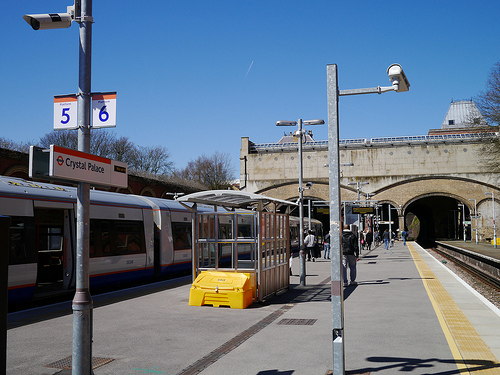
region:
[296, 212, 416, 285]
people walking along side of the tracks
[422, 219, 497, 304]
no train on the tracks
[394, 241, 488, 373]
thick yellow line on the ground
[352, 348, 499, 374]
shadow on the ground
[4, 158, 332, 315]
train on the tracks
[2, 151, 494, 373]
train at the station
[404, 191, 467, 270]
tracks running into a tunnel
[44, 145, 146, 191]
white sign on the pole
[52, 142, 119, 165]
red stripe at the top of the sign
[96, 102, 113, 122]
blue number on a white background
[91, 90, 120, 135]
the number 6 sign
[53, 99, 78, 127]
the number five sign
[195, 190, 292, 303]
the train waiting station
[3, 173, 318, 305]
the train on the side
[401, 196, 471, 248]
the hole for the train the in the wall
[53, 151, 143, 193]
the crystal palace sign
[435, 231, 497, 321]
the railway tracks on the right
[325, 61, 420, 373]
the light post in the front right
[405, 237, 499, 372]
the yellow cement line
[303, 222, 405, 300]
the people waiting in the background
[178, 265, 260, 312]
a yellow box on concrete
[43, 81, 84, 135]
A sign with the number 5 on a pole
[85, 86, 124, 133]
A sign with the number 6 on a pole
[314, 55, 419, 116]
a light at the top of a pole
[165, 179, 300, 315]
A covered area at a train station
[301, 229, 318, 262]
A person waiting for a train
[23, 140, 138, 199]
A sign for Crystal Palace on a pole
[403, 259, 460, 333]
A yellow safety line near a train track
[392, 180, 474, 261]
A train station tunnel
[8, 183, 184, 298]
A train stopped at a station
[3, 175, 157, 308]
a white red and blue passenger train car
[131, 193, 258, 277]
a white red and blue passenger train car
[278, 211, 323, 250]
a white red and blue passenger train car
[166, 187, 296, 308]
a protected train shelter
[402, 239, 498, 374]
a long yellow painted line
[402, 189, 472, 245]
an arched train tunnel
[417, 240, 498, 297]
a set of train tracks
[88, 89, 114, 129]
a train platform number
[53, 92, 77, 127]
a train platform number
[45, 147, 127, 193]
a white informational sign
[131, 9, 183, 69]
the sky is clear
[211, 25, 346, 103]
the sky is clear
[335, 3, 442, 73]
the sky is clear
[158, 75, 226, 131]
the sky is clear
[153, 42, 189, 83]
the sky is clear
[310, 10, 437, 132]
security camera attached to the pole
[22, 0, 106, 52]
security camera attached to the pole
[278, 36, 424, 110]
security camera attached to the pole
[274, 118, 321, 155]
security camera attached to the pole